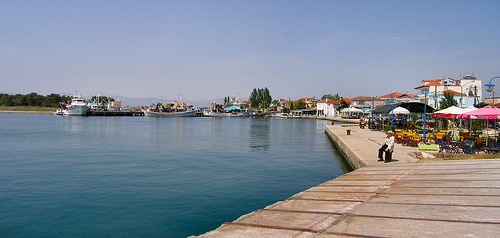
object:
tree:
[1, 92, 71, 108]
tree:
[439, 87, 458, 110]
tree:
[293, 100, 306, 110]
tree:
[321, 93, 340, 101]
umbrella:
[389, 106, 410, 115]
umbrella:
[458, 105, 500, 119]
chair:
[437, 139, 457, 153]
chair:
[460, 139, 477, 154]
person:
[378, 130, 395, 163]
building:
[414, 72, 481, 109]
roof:
[414, 77, 462, 89]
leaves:
[249, 87, 271, 109]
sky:
[2, 0, 498, 105]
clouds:
[325, 26, 409, 56]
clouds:
[117, 19, 240, 51]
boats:
[54, 89, 249, 116]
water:
[0, 113, 353, 238]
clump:
[249, 87, 272, 110]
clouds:
[192, 0, 500, 56]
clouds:
[146, 60, 240, 101]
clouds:
[6, 36, 86, 84]